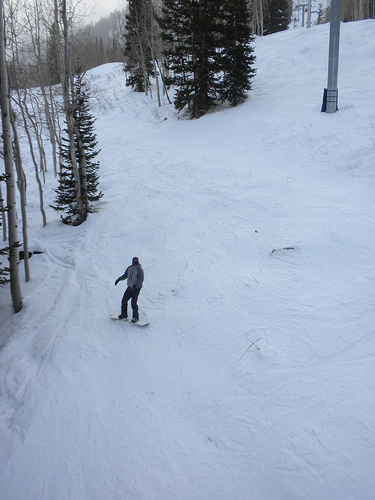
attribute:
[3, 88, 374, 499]
snow — white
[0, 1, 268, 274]
trees — healthy, green, bare